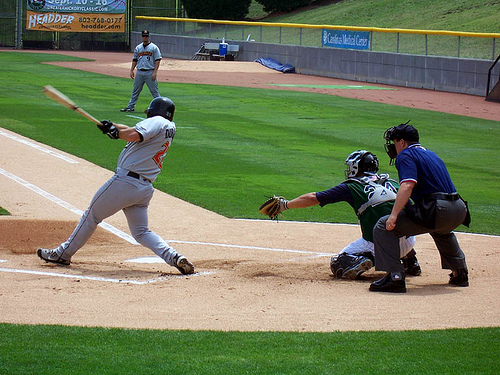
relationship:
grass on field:
[0, 49, 497, 238] [8, 3, 484, 293]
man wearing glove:
[257, 148, 427, 282] [256, 193, 286, 220]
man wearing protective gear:
[295, 115, 415, 284] [342, 147, 392, 212]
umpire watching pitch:
[357, 114, 475, 301] [5, 47, 497, 365]